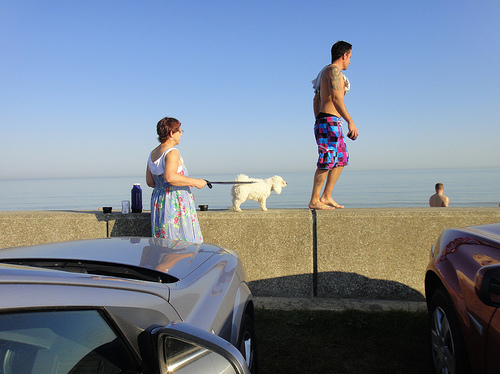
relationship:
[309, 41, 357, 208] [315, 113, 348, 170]
man wearing shorts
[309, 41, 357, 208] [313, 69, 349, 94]
man carrying shirt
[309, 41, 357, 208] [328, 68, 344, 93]
man has tattoo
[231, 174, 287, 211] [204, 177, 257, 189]
dog on leash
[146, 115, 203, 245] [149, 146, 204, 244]
woman in dress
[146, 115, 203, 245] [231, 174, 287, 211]
woman walking dog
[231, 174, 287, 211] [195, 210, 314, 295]
dog standing on ledge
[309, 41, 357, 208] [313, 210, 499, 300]
man walking on ledge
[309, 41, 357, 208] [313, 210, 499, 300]
man standing on ledge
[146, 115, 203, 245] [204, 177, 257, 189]
woman holding leash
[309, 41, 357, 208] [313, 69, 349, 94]
man has shirt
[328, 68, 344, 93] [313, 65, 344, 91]
tattoo on shoulder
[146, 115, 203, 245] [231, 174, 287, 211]
woman walking a dog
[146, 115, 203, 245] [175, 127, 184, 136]
woman wearing glasses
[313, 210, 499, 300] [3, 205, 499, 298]
ledge of wall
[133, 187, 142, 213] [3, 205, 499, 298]
bottle on wall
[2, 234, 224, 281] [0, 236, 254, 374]
hood of car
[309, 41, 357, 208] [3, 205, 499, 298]
man standing on wall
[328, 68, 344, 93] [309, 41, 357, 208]
tattoo on man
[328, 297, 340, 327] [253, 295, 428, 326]
line in sidewalk